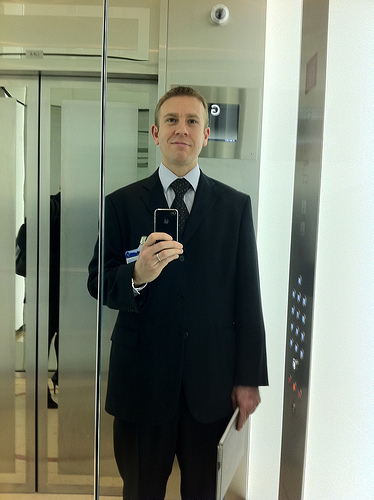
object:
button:
[178, 252, 188, 265]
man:
[83, 78, 271, 497]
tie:
[166, 178, 192, 230]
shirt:
[155, 160, 202, 244]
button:
[183, 328, 192, 340]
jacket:
[86, 163, 268, 423]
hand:
[131, 231, 181, 285]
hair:
[152, 84, 210, 131]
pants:
[114, 413, 220, 498]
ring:
[155, 252, 162, 264]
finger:
[148, 249, 184, 263]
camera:
[209, 3, 230, 28]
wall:
[153, 1, 271, 499]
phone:
[151, 204, 179, 256]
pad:
[212, 390, 254, 498]